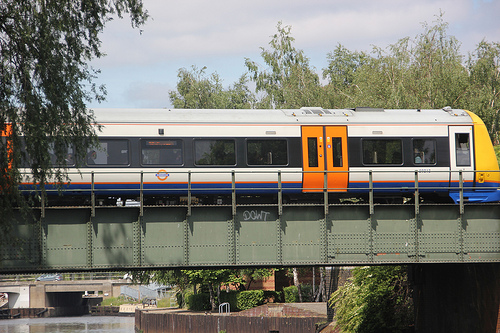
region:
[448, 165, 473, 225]
safety rail post on bridge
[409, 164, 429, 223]
safety rail post on bridge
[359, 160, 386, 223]
safety rail post on bridge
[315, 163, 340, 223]
safety rail post on bridge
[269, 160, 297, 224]
safety rail post on bridge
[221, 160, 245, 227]
safety rail post on bridge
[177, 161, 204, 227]
safety rail post on bridge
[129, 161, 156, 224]
safety rail post on bridge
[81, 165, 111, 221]
safety rail post on bridge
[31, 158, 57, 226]
safety rail post on bridge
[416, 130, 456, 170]
window on passenger train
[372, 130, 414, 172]
window on passenger train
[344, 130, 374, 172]
window on passenger train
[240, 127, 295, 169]
window on passenger train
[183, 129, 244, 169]
window on passenger train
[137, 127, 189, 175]
window on passenger train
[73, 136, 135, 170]
window on passenger train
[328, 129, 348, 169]
window on passenger train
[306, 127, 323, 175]
window on passenger train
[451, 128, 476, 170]
window on passenger train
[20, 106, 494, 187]
Train on a bridge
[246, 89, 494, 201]
Train on a bridge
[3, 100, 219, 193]
Train on a bridge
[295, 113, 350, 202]
door on a train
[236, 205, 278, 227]
graffiti on a bridge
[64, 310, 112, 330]
water under on a bridge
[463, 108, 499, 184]
yellow paint on a train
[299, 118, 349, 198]
orange doors on a train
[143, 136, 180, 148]
electric display on the train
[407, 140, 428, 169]
person sitting in the train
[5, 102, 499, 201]
A very colorful commuter train.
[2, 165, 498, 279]
A green steel bridge over a river.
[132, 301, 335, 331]
A curved river embankment with a ladder built on to it.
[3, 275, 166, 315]
A comcrete roadway bridge over a river.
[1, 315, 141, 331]
A small bit of river with many bridges over it.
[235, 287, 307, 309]
Two shubberies with a nice path between them.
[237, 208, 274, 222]
The word 'DOWT' spray painted on the rail bridge.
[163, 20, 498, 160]
A grove of trees on one side of the river.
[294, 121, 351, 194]
A pair of orange doors on the commuter train.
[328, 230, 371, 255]
A piece of steel riveted onto the bridge to make it stronger.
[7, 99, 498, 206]
train on track with a bridge over river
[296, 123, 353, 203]
yellow entry and exit doors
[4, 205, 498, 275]
bride with train track over river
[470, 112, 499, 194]
yellow end of train car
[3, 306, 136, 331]
water beneath the bridge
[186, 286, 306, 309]
green bushes near the river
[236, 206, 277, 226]
graffiti on the bridge train track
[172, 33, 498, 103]
top of trees near the bridge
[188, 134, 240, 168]
window on the train car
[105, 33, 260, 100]
blue sky above the train